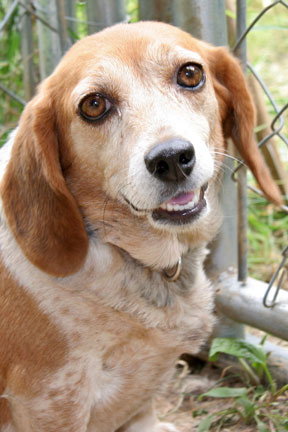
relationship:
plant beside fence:
[200, 336, 283, 431] [205, 2, 287, 388]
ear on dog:
[1, 89, 90, 278] [1, 21, 285, 431]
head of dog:
[1, 16, 282, 275] [1, 21, 285, 431]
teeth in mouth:
[160, 202, 196, 214] [156, 186, 205, 213]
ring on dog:
[164, 254, 188, 284] [1, 21, 285, 431]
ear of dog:
[210, 45, 284, 208] [1, 21, 285, 431]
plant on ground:
[200, 336, 283, 431] [157, 355, 286, 431]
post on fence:
[86, 2, 128, 37] [205, 2, 287, 388]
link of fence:
[230, 1, 278, 52] [205, 2, 287, 388]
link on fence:
[232, 173, 287, 213] [205, 2, 287, 388]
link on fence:
[263, 257, 286, 307] [205, 2, 287, 388]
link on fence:
[18, 3, 61, 32] [205, 2, 287, 388]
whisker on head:
[194, 152, 248, 164] [1, 16, 282, 275]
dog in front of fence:
[1, 21, 285, 431] [205, 2, 287, 388]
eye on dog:
[81, 95, 112, 117] [1, 21, 285, 431]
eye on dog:
[178, 64, 205, 90] [1, 21, 285, 431]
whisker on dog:
[112, 174, 141, 213] [1, 21, 285, 431]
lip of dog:
[156, 209, 205, 221] [1, 21, 285, 431]